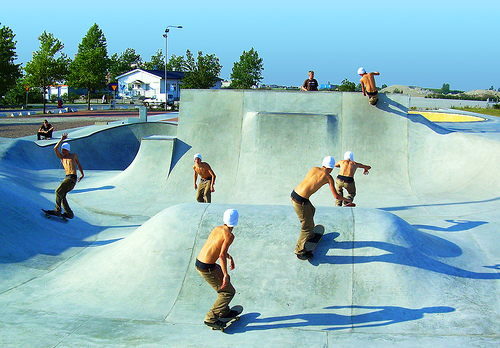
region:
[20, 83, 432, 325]
A bunch of men skateboarding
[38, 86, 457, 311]
A bunch of men skateboarding in a skateboard park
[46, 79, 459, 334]
A bunch of shirtless men skateboarding in a skateboard park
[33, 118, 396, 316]
A bunch of shirtless men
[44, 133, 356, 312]
A bunch of shirtless men in white hats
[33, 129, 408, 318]
A bunch of men all dressed the same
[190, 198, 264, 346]
A man skateboarding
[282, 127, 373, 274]
Two men skateboarding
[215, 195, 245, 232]
A white hat on a head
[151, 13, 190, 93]
A street light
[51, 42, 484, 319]
men are skateboarding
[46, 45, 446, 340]
the picture is digitally enhanced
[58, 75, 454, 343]
the same man as he skateboards a course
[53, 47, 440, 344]
six identical men on skateboards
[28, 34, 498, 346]
a skateboard course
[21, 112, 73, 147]
a person sits and watches the skateboards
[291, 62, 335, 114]
a person in a black shirt watches the skateboarders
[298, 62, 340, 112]
a man at the top of the ramp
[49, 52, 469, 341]
the skateboarder's have no shirts on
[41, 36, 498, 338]
the skateboarders all have tan pants and white hats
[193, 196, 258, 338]
man is skateboarding up ramp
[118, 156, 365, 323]
skatepark is grey concrete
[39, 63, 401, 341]
Six boys wearing same cloths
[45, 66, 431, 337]
Six boys wearing white caps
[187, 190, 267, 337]
Skater wears green pants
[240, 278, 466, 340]
Shadow of skater cast on the skate track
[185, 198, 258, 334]
Boy is bend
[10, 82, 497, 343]
Skate track is bumpy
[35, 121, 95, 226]
Skater has a hand in front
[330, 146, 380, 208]
Skater has hands in front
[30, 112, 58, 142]
Viewer sits on side of skate track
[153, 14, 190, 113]
Light pole on street